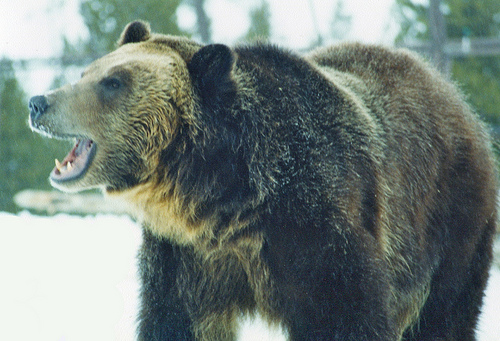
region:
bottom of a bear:
[256, 280, 264, 294]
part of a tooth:
[61, 160, 68, 163]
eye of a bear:
[111, 78, 126, 95]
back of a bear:
[415, 198, 440, 220]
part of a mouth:
[120, 173, 134, 193]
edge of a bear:
[175, 112, 219, 192]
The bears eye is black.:
[106, 75, 123, 91]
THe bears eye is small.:
[109, 73, 122, 90]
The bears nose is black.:
[25, 94, 46, 113]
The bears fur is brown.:
[276, 94, 397, 166]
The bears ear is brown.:
[193, 43, 237, 85]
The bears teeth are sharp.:
[51, 158, 77, 170]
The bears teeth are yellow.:
[53, 154, 76, 172]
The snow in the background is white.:
[36, 228, 122, 293]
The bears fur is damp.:
[300, 100, 388, 165]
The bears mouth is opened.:
[25, 24, 204, 188]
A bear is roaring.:
[16, 18, 260, 239]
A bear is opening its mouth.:
[11, 20, 292, 241]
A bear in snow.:
[3, 0, 498, 337]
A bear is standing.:
[16, 23, 498, 340]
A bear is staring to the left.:
[0, 20, 237, 197]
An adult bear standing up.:
[5, 25, 480, 335]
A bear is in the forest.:
[1, 2, 488, 337]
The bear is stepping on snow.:
[21, 17, 492, 338]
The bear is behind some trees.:
[0, 0, 496, 233]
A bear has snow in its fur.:
[22, 28, 499, 282]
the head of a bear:
[22, 16, 239, 201]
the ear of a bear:
[115, 15, 155, 44]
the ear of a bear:
[191, 38, 240, 95]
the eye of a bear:
[98, 74, 125, 93]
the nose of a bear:
[25, 93, 52, 118]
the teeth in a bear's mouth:
[50, 158, 76, 173]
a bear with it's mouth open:
[26, 30, 232, 202]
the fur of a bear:
[250, 108, 310, 180]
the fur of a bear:
[143, 200, 168, 225]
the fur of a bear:
[413, 90, 452, 160]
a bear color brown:
[13, 8, 496, 339]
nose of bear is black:
[19, 90, 56, 117]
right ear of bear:
[185, 36, 241, 91]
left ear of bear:
[106, 10, 156, 50]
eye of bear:
[97, 66, 123, 91]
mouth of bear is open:
[22, 97, 102, 187]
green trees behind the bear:
[1, 3, 493, 257]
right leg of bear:
[263, 285, 398, 338]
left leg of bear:
[127, 285, 240, 340]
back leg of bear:
[424, 260, 491, 337]